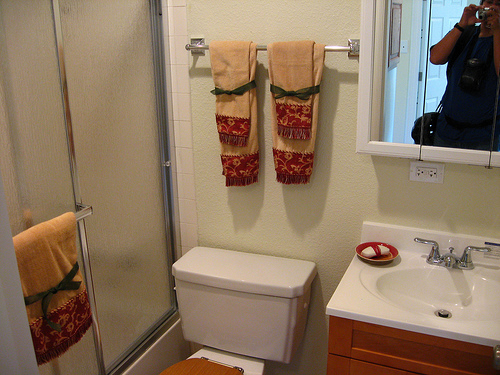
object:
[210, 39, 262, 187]
towel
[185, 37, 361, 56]
holder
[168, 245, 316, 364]
sink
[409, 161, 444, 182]
outlet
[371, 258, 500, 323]
sink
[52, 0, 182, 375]
door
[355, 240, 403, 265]
dish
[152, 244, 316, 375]
toilet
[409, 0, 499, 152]
man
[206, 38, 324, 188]
towels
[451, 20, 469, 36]
watch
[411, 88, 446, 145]
bag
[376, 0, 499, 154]
mirror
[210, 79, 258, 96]
ribbon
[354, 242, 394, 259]
soap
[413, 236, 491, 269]
faucet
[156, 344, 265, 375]
seat